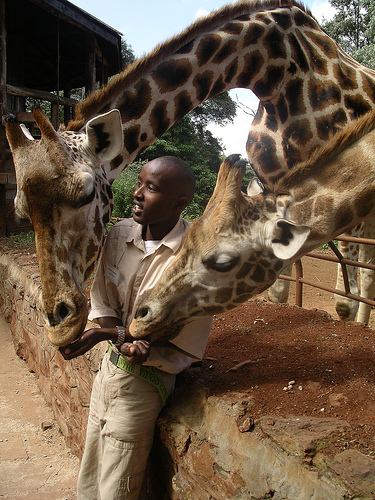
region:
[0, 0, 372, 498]
Two giraffes and a man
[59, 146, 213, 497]
Man standing between two giraffes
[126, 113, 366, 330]
Giraffe to the left of the man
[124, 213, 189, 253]
Collar of the shirt the man is wearing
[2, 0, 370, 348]
Giraffe to the right side of the man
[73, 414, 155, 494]
Beige pants of man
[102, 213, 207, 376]
Light cream colored shirt man is wearing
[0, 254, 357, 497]
Half brick wall in back of the man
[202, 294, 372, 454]
Red dirt in back of the man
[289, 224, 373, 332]
Wood fence between man and the giraffes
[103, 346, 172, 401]
a yellow belt on a man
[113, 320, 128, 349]
a silver watch on a man's arm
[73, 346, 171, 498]
tan pants on a man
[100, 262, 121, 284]
a name tag on a man's shirt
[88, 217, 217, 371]
a tan shirt on a man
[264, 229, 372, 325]
a railing in front of giraffes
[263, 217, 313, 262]
the ear of a giraffe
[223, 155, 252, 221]
the black tipped horn of a giraffe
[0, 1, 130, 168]
a structure by a giraffe pen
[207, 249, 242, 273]
the eye of a giraffe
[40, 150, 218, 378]
this guy is feeding two giraffes at once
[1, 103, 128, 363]
giraffe getting a snack from the man's hand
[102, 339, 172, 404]
this young man is wearing a green belt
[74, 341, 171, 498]
this young man is wearing khaki pants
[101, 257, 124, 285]
this young man is wearing a name tag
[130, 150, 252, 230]
the giraffe's horns are as big as the man's head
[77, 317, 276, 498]
the man is leaning against a stone wall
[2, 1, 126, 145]
some kind of building next to the giraffe pen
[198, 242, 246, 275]
giraffes have very gentle eyes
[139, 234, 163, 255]
this man is wearing a t-shirt under his uniform shirt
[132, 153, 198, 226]
The man's hair is black.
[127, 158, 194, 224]
The man's hair is short.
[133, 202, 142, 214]
The man's teeth are white.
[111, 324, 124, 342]
The man is wearing a watch.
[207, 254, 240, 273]
The giraffes eye is black.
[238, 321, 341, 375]
The dirt is red in color.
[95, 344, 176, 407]
The man is wearing a green belt.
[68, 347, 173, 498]
The man is wearing tan pants.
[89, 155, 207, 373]
The man is wearing a tan shirt.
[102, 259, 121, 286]
The man is wearing a badge.